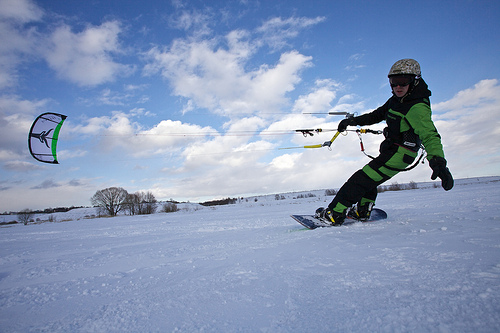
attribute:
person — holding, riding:
[317, 59, 455, 225]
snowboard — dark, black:
[290, 201, 392, 230]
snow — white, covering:
[3, 178, 500, 330]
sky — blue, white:
[0, 0, 498, 216]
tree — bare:
[92, 187, 127, 215]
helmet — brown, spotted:
[387, 56, 422, 77]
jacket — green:
[349, 95, 451, 158]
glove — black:
[430, 156, 455, 192]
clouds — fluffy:
[151, 24, 334, 113]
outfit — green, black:
[330, 101, 444, 216]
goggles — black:
[389, 74, 416, 87]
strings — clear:
[61, 130, 338, 141]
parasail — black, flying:
[26, 111, 65, 164]